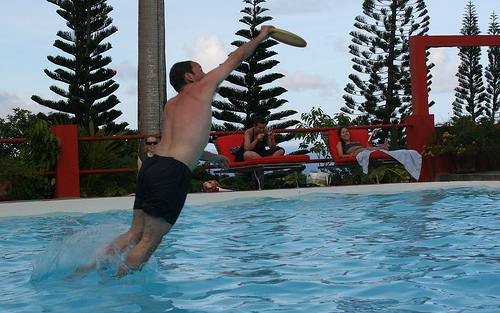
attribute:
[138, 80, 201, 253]
man — jumping, wet, reaching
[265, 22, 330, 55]
frisbee — yellow, white, toy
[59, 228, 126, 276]
water — splashing, clean, blue, bright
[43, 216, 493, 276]
water — calm, blue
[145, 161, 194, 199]
shorts — black, wet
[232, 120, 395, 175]
people — three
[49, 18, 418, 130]
trees — tall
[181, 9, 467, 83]
sky — blue, cloudy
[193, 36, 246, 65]
clouds — white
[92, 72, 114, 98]
leaves — green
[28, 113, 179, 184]
fence — red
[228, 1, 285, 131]
tree — growing, pine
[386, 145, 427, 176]
towel — white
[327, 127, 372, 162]
woman — lounging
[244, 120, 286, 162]
lady — relaxing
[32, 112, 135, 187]
railing — red, mettalic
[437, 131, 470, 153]
flowers — growing, yellow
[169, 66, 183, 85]
hair — black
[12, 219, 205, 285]
waves — moving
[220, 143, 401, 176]
chairs — red